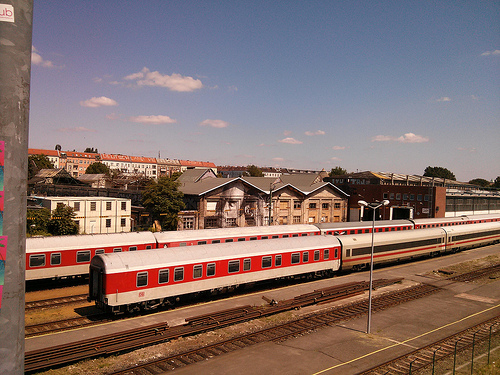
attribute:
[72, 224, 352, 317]
passenger car — white, red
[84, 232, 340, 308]
cabin — red, white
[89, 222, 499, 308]
cars — train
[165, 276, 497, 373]
road — murram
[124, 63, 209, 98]
cloud — small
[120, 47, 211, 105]
cloud — white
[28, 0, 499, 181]
sky — blue, clear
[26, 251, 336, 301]
car — passenger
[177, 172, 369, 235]
building — white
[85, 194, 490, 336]
train — red, silver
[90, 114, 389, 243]
building — red, brick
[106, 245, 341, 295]
stripe — red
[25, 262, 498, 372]
tracks — train, rusty